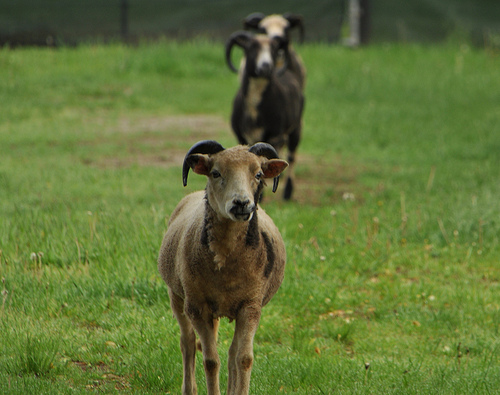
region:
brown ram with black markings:
[127, 123, 297, 394]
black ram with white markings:
[207, 28, 316, 203]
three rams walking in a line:
[167, 3, 307, 392]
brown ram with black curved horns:
[133, 125, 309, 391]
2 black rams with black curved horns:
[210, 7, 317, 200]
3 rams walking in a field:
[142, 12, 323, 387]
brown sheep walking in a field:
[135, 136, 310, 393]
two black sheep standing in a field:
[216, 11, 326, 218]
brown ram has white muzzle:
[148, 127, 310, 393]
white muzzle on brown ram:
[210, 164, 261, 226]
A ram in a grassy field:
[150, 132, 305, 393]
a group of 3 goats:
[143, 10, 315, 393]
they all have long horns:
[159, 5, 314, 205]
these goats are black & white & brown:
[233, 14, 313, 146]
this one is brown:
[130, 113, 304, 385]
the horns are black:
[152, 121, 299, 192]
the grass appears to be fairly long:
[33, 36, 448, 176]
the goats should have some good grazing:
[31, 33, 193, 107]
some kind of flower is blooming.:
[324, 175, 419, 316]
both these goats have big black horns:
[212, 5, 314, 85]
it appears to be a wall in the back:
[23, 2, 185, 49]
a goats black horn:
[180, 138, 225, 188]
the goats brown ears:
[259, 159, 289, 176]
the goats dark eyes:
[253, 171, 263, 182]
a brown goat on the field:
[157, 139, 288, 394]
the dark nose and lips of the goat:
[228, 197, 255, 222]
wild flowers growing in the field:
[295, 190, 499, 260]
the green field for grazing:
[309, 44, 499, 394]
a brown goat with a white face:
[223, 31, 305, 144]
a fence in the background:
[0, 1, 225, 46]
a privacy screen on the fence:
[307, 2, 499, 50]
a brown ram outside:
[155, 133, 304, 394]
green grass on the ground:
[376, 347, 447, 387]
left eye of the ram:
[250, 168, 264, 183]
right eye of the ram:
[208, 168, 221, 184]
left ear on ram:
[262, 154, 291, 183]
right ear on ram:
[188, 148, 206, 182]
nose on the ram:
[232, 188, 250, 208]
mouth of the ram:
[230, 206, 254, 219]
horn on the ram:
[248, 143, 284, 177]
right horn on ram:
[165, 132, 227, 183]